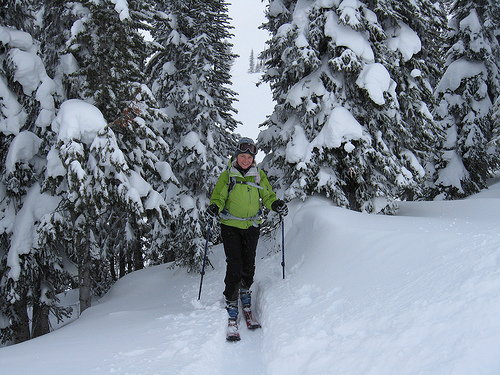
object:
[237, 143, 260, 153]
goggles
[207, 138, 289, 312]
woman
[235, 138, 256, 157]
hat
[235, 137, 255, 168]
head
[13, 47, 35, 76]
snow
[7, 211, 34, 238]
snow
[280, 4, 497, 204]
tree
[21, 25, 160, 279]
tree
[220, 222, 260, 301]
pants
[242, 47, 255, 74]
tree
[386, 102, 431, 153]
pine needles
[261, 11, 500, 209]
snow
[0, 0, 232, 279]
pine trees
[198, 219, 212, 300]
pole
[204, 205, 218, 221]
hand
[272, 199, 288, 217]
gloves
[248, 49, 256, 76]
tree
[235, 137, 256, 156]
hair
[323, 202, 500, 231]
snow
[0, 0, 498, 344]
trees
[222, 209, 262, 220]
skier's belt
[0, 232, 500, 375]
snow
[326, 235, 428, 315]
ground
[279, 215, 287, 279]
pole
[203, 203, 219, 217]
glove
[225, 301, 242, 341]
ski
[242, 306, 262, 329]
ski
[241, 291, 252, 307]
foot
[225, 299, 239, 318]
foot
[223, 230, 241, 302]
leg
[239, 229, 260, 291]
leg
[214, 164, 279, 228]
coat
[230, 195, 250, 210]
green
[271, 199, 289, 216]
hand